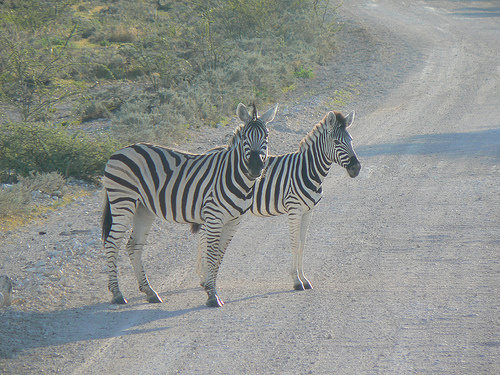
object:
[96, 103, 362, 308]
two zebras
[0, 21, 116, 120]
tree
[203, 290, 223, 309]
hoofs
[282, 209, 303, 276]
leg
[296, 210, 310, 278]
leg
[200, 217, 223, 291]
leg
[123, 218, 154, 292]
leg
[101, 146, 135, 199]
hind quarters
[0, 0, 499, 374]
dirt road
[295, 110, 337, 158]
mane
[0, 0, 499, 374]
floor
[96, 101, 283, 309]
animal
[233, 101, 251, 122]
ear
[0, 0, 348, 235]
grass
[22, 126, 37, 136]
leaves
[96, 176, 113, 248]
tail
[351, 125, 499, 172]
shadow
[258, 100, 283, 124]
ears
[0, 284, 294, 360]
shadow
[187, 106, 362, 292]
zebra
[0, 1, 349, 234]
brush